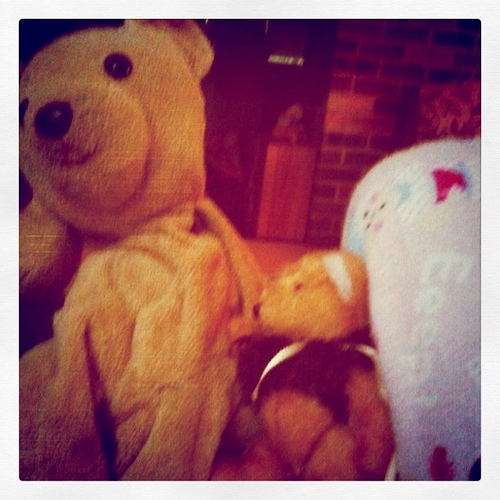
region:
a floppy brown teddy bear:
[20, 20, 368, 478]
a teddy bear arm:
[19, 193, 75, 290]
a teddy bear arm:
[207, 201, 373, 341]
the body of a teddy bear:
[62, 226, 229, 460]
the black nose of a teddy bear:
[35, 96, 71, 131]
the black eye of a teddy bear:
[20, 95, 31, 121]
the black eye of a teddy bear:
[102, 50, 128, 76]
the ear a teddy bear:
[121, 20, 216, 71]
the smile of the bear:
[46, 140, 107, 170]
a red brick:
[329, 57, 380, 73]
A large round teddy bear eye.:
[102, 52, 134, 78]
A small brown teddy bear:
[218, 245, 395, 480]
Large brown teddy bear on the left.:
[16, 17, 263, 482]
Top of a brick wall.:
[336, 20, 480, 166]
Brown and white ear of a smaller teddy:
[323, 248, 367, 305]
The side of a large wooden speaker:
[252, 132, 315, 244]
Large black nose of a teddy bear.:
[32, 101, 73, 139]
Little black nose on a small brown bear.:
[252, 300, 261, 318]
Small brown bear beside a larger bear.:
[215, 250, 394, 487]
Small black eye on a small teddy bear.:
[292, 280, 304, 293]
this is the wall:
[341, 52, 376, 129]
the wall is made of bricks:
[343, 40, 397, 150]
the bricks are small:
[346, 55, 396, 98]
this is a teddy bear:
[21, 24, 246, 458]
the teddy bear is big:
[23, 27, 215, 249]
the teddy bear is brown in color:
[146, 90, 193, 170]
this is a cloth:
[401, 212, 458, 319]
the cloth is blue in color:
[396, 155, 416, 171]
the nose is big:
[38, 103, 71, 130]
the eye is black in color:
[105, 54, 130, 76]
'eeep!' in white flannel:
[387, 236, 477, 416]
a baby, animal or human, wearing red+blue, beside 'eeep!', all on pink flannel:
[342, 150, 477, 262]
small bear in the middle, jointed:
[185, 235, 400, 485]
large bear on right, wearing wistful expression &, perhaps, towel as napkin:
[15, 20, 255, 480]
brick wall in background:
[302, 20, 477, 261]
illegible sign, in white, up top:
[257, 50, 308, 68]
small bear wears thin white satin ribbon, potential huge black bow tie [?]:
[205, 325, 390, 426]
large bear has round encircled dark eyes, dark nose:
[16, 41, 146, 147]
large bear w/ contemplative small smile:
[35, 137, 108, 170]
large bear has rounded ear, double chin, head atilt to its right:
[13, 18, 230, 247]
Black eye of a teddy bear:
[101, 52, 134, 80]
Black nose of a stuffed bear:
[29, 100, 79, 142]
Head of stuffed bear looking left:
[246, 240, 368, 342]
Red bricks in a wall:
[306, 137, 356, 244]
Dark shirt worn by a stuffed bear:
[246, 339, 372, 418]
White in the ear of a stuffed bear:
[317, 251, 357, 305]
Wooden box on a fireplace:
[255, 132, 320, 247]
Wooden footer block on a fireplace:
[226, 230, 346, 289]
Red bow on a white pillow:
[426, 167, 470, 212]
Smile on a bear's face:
[40, 142, 115, 175]